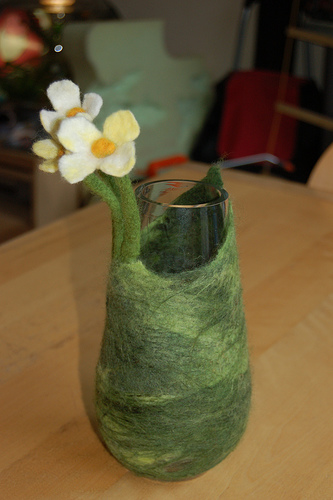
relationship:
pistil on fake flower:
[92, 136, 117, 159] [58, 108, 140, 183]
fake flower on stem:
[34, 77, 141, 182] [86, 174, 139, 268]